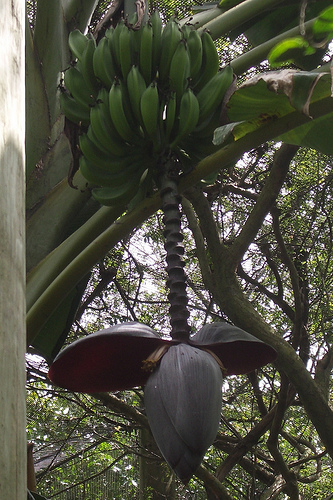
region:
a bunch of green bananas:
[67, 11, 227, 190]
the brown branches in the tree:
[230, 401, 315, 490]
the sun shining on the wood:
[0, 8, 23, 132]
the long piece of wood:
[1, 2, 27, 492]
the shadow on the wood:
[0, 133, 23, 497]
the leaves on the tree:
[291, 164, 331, 265]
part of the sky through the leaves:
[131, 238, 162, 267]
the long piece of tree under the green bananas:
[160, 156, 190, 332]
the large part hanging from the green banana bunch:
[44, 325, 276, 484]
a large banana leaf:
[228, 68, 328, 145]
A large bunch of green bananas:
[58, 9, 233, 206]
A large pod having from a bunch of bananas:
[46, 160, 278, 488]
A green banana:
[124, 64, 147, 125]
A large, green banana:
[107, 78, 149, 146]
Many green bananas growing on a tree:
[57, 10, 232, 212]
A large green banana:
[195, 61, 233, 124]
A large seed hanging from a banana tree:
[142, 342, 222, 486]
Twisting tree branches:
[176, 139, 325, 496]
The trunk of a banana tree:
[0, 0, 25, 496]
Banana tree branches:
[25, 0, 331, 347]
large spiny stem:
[153, 194, 212, 336]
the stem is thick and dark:
[148, 191, 200, 340]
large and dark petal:
[28, 294, 173, 400]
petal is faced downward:
[129, 327, 229, 492]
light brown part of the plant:
[129, 337, 182, 377]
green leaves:
[30, 388, 89, 448]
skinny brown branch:
[48, 443, 127, 499]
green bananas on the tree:
[41, 0, 248, 199]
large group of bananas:
[47, 12, 242, 212]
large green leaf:
[216, 50, 330, 154]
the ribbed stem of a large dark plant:
[160, 159, 190, 342]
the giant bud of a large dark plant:
[143, 344, 218, 481]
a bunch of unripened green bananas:
[66, 17, 236, 198]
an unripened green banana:
[168, 37, 188, 91]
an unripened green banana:
[106, 73, 134, 140]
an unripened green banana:
[127, 64, 146, 116]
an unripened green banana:
[200, 28, 219, 79]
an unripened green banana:
[198, 66, 232, 113]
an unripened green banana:
[68, 27, 88, 56]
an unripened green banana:
[92, 178, 143, 203]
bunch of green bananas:
[66, 10, 216, 152]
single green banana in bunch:
[142, 83, 162, 142]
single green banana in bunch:
[107, 82, 135, 140]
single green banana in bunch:
[172, 44, 186, 85]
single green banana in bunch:
[88, 104, 117, 152]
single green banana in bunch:
[98, 33, 109, 78]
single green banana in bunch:
[204, 31, 217, 75]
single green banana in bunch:
[142, 19, 153, 67]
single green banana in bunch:
[119, 16, 131, 64]